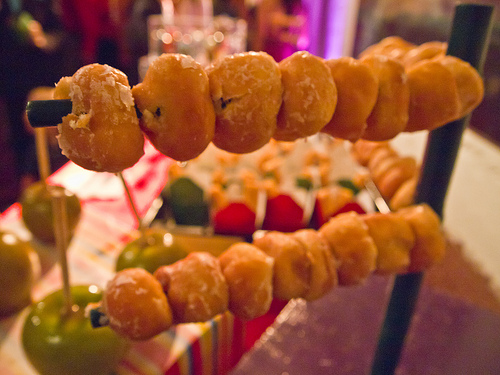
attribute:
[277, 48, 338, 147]
doughnut hole — glazed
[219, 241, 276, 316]
doughnut hole — glazed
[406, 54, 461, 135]
doughnut hole — glazed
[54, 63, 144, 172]
doughnut hole — glazed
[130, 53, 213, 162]
doughnut hole — glazed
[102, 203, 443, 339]
pastry — horizontal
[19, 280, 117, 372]
apple — candy, green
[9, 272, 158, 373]
apple — green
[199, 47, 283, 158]
doughnut — glazed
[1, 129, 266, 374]
table cloth — striped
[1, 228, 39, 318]
apple — green, candy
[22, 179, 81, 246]
apple — green, candy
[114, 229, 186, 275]
apple — green, candy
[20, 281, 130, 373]
apple — green, candy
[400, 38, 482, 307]
pole — black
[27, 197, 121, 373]
candy apple — green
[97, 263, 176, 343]
doughnut hole — glazed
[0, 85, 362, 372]
tablecloth — striped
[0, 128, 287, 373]
tablecloth — multicolored, striped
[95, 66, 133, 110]
glaze — white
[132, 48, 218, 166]
doughnut — glazed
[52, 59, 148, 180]
pastry — glazed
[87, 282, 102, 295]
light — glimming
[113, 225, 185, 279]
candy apple — green